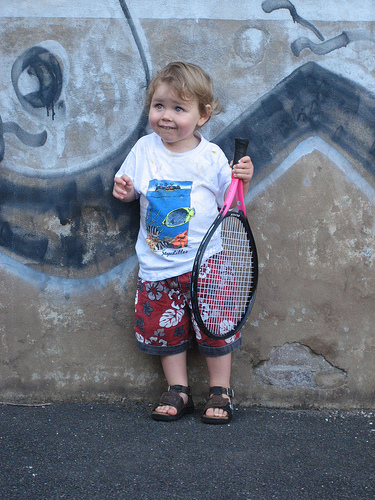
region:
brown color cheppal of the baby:
[145, 379, 246, 428]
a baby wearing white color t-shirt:
[117, 134, 240, 272]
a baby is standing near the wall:
[99, 96, 270, 436]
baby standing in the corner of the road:
[117, 29, 271, 439]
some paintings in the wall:
[248, 14, 363, 237]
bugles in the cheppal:
[226, 387, 238, 397]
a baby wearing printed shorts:
[131, 250, 249, 351]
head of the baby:
[144, 50, 212, 143]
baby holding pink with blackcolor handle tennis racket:
[94, 143, 268, 203]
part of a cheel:
[177, 115, 193, 133]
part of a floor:
[254, 435, 277, 474]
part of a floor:
[236, 434, 272, 489]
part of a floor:
[262, 433, 289, 475]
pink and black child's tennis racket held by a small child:
[190, 136, 259, 339]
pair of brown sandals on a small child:
[151, 384, 236, 424]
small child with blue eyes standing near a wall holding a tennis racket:
[112, 60, 254, 423]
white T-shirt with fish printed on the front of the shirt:
[115, 127, 235, 282]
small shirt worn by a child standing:
[112, 129, 237, 281]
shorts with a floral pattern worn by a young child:
[133, 249, 244, 356]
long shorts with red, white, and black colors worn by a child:
[133, 249, 243, 355]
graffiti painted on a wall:
[0, 0, 373, 288]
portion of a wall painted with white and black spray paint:
[0, 0, 373, 293]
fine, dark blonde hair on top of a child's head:
[147, 60, 223, 119]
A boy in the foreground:
[107, 54, 262, 429]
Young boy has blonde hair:
[129, 60, 226, 121]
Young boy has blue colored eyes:
[148, 95, 187, 118]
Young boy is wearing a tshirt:
[96, 126, 254, 289]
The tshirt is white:
[101, 129, 262, 290]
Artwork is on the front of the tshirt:
[135, 176, 203, 262]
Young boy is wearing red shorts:
[120, 246, 255, 370]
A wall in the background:
[2, 2, 369, 407]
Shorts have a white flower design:
[125, 256, 260, 352]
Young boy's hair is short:
[132, 52, 225, 131]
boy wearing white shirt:
[110, 126, 246, 281]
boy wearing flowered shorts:
[112, 252, 257, 363]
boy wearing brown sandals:
[144, 379, 252, 427]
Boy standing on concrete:
[97, 54, 269, 435]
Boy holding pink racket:
[185, 130, 263, 346]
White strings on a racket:
[226, 269, 245, 290]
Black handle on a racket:
[230, 134, 252, 155]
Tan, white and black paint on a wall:
[18, 151, 79, 290]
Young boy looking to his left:
[132, 56, 222, 149]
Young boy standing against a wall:
[104, 49, 262, 286]